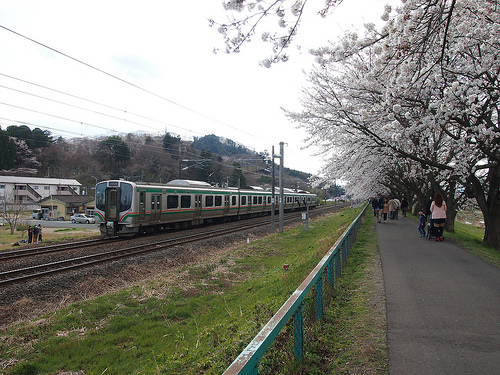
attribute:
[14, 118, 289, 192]
trees — white 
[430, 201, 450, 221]
blazer — pink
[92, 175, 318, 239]
passenger train — green, orange, white, silver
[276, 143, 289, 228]
pole — wood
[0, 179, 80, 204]
building — white, apartment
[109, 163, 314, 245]
train — electric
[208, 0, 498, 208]
cherry blossom — trees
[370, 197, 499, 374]
walkway — smooth, blacktop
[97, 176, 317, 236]
train — long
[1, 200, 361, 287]
train track — going into distance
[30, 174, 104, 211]
roof — grey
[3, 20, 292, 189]
lines — utility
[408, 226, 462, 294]
shoes — red